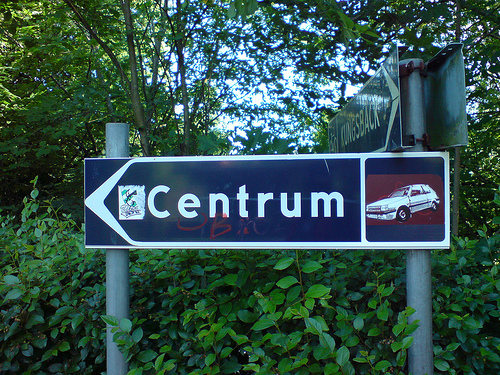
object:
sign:
[327, 40, 471, 154]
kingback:
[336, 93, 383, 148]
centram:
[148, 181, 348, 223]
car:
[365, 182, 440, 222]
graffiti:
[175, 206, 265, 238]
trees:
[12, 1, 192, 144]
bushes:
[3, 157, 500, 375]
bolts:
[402, 58, 430, 149]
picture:
[4, 9, 499, 362]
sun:
[277, 37, 376, 124]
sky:
[151, 8, 500, 146]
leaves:
[33, 138, 62, 158]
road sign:
[79, 147, 453, 249]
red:
[366, 177, 392, 195]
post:
[101, 120, 137, 366]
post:
[401, 51, 436, 370]